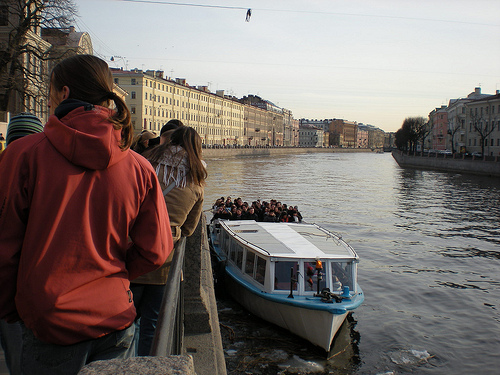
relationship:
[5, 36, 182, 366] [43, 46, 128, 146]
person has head